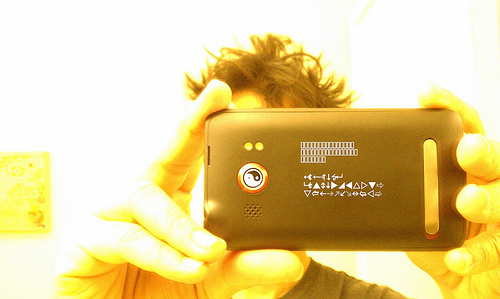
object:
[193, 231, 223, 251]
nail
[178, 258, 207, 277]
nail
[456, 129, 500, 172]
nail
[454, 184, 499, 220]
nail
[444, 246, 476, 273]
nail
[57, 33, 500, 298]
man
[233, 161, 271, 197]
camera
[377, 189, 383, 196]
white symbol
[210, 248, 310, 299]
fingers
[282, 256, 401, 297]
t-shirt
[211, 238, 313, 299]
thumb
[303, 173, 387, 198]
symbol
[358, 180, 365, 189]
tail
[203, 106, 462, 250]
cell phone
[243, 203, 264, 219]
ear piece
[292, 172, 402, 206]
writing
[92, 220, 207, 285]
finger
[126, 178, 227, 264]
finger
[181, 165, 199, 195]
finger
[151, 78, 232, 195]
finger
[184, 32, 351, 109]
hair